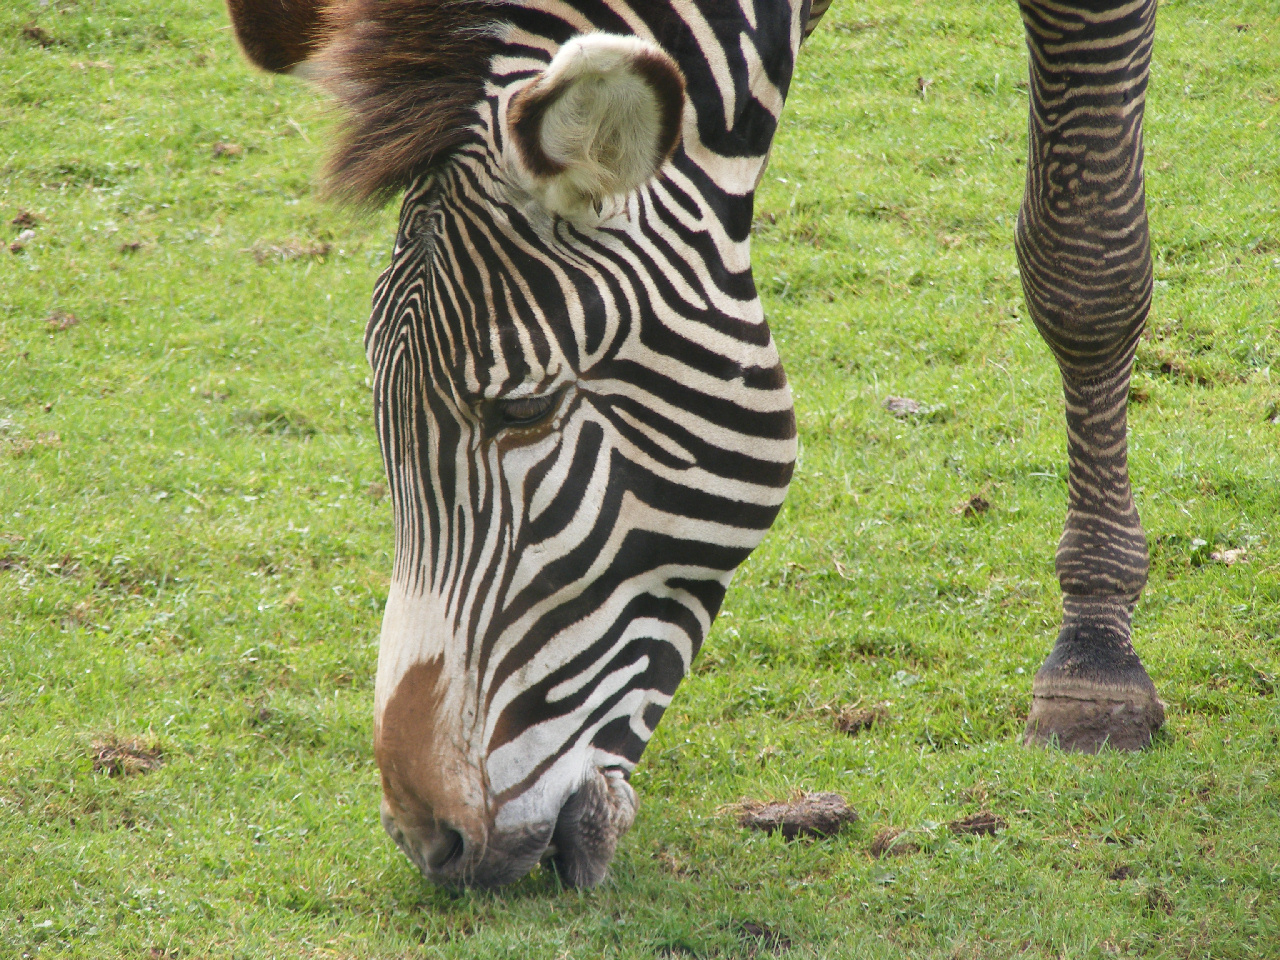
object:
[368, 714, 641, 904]
mouth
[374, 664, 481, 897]
nose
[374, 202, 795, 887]
face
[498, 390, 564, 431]
eye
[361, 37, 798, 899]
zebra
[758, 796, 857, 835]
grass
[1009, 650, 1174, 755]
hoof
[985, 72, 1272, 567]
leg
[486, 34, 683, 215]
ear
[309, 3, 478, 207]
mane